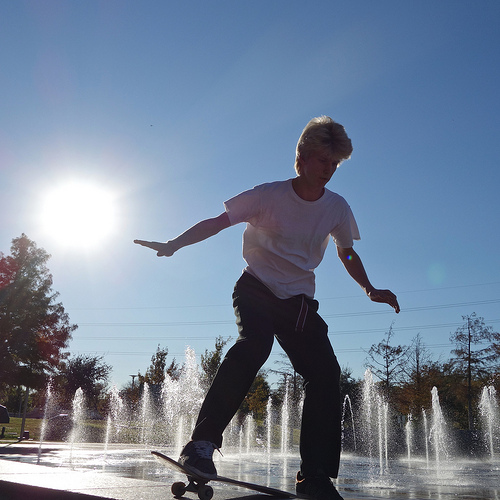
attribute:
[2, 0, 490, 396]
sky — blue , clear 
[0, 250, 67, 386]
leaves — green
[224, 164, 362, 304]
shirt — white, sleeved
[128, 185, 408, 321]
arms — raised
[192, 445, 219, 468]
laces — white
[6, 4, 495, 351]
sky — bright blue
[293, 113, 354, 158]
hair — blonde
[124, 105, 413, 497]
person — blond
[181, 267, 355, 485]
pants — dark-colored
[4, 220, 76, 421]
tree — green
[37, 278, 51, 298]
leaves — red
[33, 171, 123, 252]
sun — bright, shining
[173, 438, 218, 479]
shoe — black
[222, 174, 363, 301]
t-shirt — white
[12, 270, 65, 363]
leaves — green 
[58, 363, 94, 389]
leaves — green 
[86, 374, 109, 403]
leaves — green 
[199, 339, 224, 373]
leaves — green 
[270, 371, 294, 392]
leaves — green 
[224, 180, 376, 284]
shirt — white 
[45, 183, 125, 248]
sun — bright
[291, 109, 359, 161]
hair — blonde 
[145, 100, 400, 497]
man — young 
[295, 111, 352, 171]
hair — blonde 